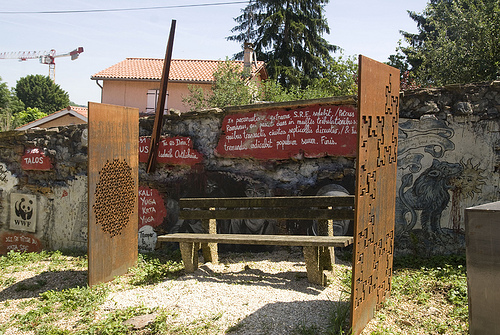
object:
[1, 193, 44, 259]
sign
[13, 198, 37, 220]
panda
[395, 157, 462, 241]
painting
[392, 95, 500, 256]
wall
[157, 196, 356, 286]
bench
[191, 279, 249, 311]
sand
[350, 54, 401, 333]
planks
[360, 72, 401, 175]
designs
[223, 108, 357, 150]
writing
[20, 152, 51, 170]
sign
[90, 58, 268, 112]
building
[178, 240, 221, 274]
legs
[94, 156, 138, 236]
designs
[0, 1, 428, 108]
sky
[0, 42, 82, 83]
crane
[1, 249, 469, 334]
floor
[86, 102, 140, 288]
board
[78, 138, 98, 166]
edge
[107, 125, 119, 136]
surface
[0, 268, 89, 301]
shade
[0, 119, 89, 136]
fence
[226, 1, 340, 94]
tree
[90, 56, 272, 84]
roof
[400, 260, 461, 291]
grass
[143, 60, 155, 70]
tile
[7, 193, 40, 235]
poster